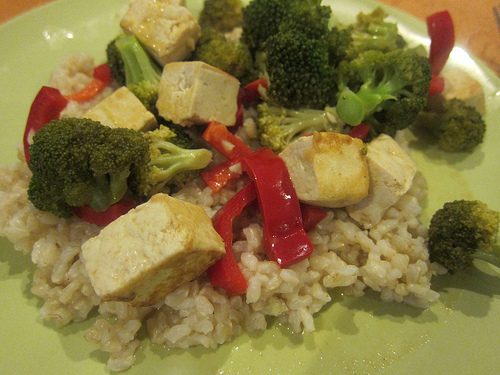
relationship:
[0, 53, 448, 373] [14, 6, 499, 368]
rice on plate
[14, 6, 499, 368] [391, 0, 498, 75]
plate on table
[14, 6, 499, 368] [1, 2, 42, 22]
plate on table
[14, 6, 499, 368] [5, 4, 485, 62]
plate on table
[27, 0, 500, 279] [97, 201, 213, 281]
broccoli on chicken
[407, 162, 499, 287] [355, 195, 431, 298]
broccoli near rice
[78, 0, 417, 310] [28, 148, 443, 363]
chicken on top of rice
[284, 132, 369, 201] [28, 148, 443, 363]
chicken on top of rice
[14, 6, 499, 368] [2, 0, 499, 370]
plate full of food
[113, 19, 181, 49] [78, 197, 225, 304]
sauce on chicken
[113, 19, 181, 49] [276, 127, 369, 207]
sauce on chicken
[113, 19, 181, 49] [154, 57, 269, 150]
sauce on chicken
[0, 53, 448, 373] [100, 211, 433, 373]
rice on rice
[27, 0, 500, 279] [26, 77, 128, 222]
broccoli on tomato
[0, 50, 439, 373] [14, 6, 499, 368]
rice on plate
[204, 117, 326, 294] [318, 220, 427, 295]
peppers on rice